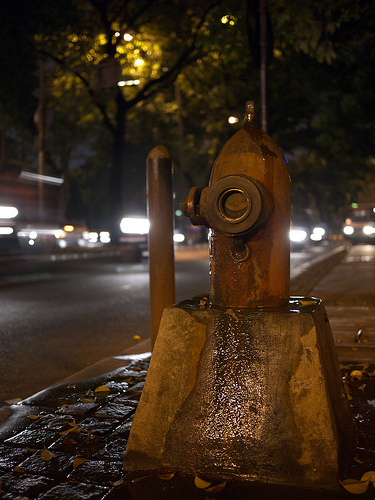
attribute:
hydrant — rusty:
[182, 119, 293, 311]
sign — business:
[35, 55, 126, 223]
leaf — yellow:
[92, 382, 111, 392]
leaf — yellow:
[25, 412, 39, 420]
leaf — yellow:
[51, 413, 82, 438]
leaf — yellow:
[348, 368, 364, 381]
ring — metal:
[229, 239, 253, 265]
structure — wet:
[59, 106, 355, 473]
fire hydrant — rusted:
[179, 101, 296, 307]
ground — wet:
[3, 365, 372, 497]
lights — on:
[1, 200, 374, 251]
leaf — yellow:
[337, 477, 372, 494]